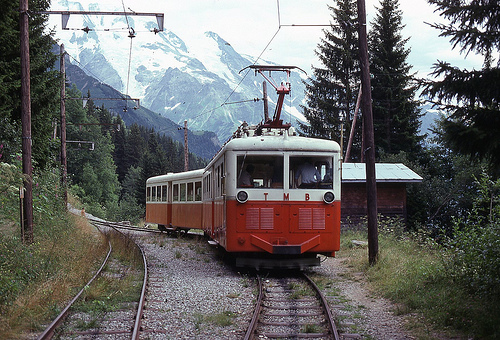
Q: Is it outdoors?
A: Yes, it is outdoors.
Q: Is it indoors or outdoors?
A: It is outdoors.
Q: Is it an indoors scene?
A: No, it is outdoors.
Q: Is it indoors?
A: No, it is outdoors.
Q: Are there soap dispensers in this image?
A: No, there are no soap dispensers.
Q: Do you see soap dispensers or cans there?
A: No, there are no soap dispensers or cans.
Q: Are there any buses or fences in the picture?
A: No, there are no fences or buses.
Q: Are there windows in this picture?
A: Yes, there is a window.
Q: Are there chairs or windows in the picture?
A: Yes, there is a window.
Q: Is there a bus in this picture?
A: No, there are no buses.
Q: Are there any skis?
A: No, there are no skis.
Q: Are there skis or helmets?
A: No, there are no skis or helmets.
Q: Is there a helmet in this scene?
A: No, there are no helmets.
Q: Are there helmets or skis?
A: No, there are no helmets or skis.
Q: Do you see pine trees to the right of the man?
A: Yes, there is a pine tree to the right of the man.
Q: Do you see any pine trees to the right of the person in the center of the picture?
A: Yes, there is a pine tree to the right of the man.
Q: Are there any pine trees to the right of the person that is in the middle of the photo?
A: Yes, there is a pine tree to the right of the man.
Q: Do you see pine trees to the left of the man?
A: No, the pine tree is to the right of the man.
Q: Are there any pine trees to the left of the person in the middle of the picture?
A: No, the pine tree is to the right of the man.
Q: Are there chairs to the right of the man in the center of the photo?
A: No, there is a pine tree to the right of the man.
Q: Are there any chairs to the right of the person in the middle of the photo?
A: No, there is a pine tree to the right of the man.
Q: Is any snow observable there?
A: Yes, there is snow.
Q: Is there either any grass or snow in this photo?
A: Yes, there is snow.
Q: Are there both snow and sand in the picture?
A: No, there is snow but no sand.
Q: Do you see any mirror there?
A: No, there are no mirrors.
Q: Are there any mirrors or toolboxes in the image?
A: No, there are no mirrors or toolboxes.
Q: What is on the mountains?
A: The snow is on the mountains.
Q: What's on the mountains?
A: The snow is on the mountains.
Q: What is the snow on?
A: The snow is on the mountains.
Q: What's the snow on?
A: The snow is on the mountains.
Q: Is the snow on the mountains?
A: Yes, the snow is on the mountains.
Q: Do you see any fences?
A: No, there are no fences.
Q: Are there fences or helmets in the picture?
A: No, there are no fences or helmets.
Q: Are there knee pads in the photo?
A: No, there are no knee pads.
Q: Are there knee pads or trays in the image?
A: No, there are no knee pads or trays.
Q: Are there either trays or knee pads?
A: No, there are no knee pads or trays.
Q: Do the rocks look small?
A: Yes, the rocks are small.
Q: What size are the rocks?
A: The rocks are small.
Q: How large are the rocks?
A: The rocks are small.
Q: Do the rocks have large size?
A: No, the rocks are small.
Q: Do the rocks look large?
A: No, the rocks are small.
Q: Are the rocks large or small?
A: The rocks are small.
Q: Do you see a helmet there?
A: No, there are no helmets.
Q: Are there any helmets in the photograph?
A: No, there are no helmets.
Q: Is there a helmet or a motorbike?
A: No, there are no helmets or motorcycles.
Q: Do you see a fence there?
A: No, there are no fences.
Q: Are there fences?
A: No, there are no fences.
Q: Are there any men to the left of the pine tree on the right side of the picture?
A: Yes, there is a man to the left of the pine.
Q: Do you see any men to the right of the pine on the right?
A: No, the man is to the left of the pine.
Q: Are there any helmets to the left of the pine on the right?
A: No, there is a man to the left of the pine tree.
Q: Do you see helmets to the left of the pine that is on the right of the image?
A: No, there is a man to the left of the pine tree.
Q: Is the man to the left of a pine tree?
A: Yes, the man is to the left of a pine tree.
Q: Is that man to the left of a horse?
A: No, the man is to the left of a pine tree.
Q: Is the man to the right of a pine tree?
A: No, the man is to the left of a pine tree.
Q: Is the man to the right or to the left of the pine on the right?
A: The man is to the left of the pine tree.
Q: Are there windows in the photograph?
A: Yes, there is a window.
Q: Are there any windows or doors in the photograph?
A: Yes, there is a window.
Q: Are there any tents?
A: No, there are no tents.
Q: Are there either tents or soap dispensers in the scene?
A: No, there are no tents or soap dispensers.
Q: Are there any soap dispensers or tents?
A: No, there are no tents or soap dispensers.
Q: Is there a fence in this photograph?
A: No, there are no fences.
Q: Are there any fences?
A: No, there are no fences.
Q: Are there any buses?
A: No, there are no buses.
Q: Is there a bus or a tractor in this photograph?
A: No, there are no buses or tractors.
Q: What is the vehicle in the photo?
A: The vehicle is a car.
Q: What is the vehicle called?
A: The vehicle is a car.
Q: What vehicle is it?
A: The vehicle is a car.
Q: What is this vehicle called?
A: This is a car.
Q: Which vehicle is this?
A: This is a car.